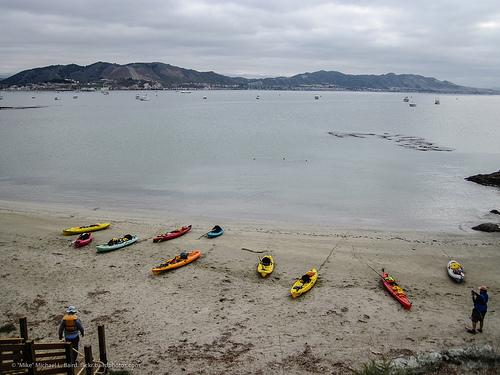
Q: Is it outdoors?
A: Yes, it is outdoors.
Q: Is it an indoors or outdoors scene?
A: It is outdoors.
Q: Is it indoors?
A: No, it is outdoors.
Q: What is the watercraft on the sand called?
A: The watercraft is a canoe.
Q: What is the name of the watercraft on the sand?
A: The watercraft is a canoe.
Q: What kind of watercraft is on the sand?
A: The watercraft is a canoe.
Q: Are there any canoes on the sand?
A: Yes, there is a canoe on the sand.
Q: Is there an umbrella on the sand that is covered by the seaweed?
A: No, there is a canoe on the sand.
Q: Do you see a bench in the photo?
A: No, there are no benches.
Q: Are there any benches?
A: No, there are no benches.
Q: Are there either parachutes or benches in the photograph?
A: No, there are no benches or parachutes.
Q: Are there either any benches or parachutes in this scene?
A: No, there are no benches or parachutes.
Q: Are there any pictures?
A: No, there are no pictures.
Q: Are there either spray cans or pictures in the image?
A: No, there are no pictures or spray cans.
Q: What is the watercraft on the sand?
A: The watercraft is a canoe.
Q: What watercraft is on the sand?
A: The watercraft is a canoe.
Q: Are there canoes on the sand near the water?
A: Yes, there is a canoe on the sand.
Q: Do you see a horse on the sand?
A: No, there is a canoe on the sand.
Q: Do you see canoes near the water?
A: Yes, there is a canoe near the water.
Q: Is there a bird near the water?
A: No, there is a canoe near the water.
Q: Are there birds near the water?
A: No, there is a canoe near the water.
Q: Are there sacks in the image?
A: No, there are no sacks.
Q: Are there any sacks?
A: No, there are no sacks.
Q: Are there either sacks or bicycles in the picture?
A: No, there are no sacks or bicycles.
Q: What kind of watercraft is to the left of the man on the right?
A: The watercraft is a canoe.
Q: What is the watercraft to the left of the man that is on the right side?
A: The watercraft is a canoe.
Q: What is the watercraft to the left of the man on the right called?
A: The watercraft is a canoe.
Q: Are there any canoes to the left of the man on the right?
A: Yes, there is a canoe to the left of the man.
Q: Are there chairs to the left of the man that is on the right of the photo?
A: No, there is a canoe to the left of the man.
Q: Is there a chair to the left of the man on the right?
A: No, there is a canoe to the left of the man.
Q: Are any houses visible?
A: No, there are no houses.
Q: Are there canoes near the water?
A: Yes, there is a canoe near the water.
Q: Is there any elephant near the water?
A: No, there is a canoe near the water.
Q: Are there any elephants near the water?
A: No, there is a canoe near the water.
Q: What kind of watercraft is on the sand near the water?
A: The watercraft is a canoe.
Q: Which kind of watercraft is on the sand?
A: The watercraft is a canoe.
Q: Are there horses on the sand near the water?
A: No, there is a canoe on the sand.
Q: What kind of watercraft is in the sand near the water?
A: The watercraft is a canoe.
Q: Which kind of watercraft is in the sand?
A: The watercraft is a canoe.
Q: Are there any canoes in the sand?
A: Yes, there is a canoe in the sand.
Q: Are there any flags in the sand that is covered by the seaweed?
A: No, there is a canoe in the sand.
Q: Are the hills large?
A: Yes, the hills are large.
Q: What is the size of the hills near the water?
A: The hills are large.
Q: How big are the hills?
A: The hills are large.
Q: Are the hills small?
A: No, the hills are large.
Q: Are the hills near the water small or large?
A: The hills are large.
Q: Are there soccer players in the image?
A: No, there are no soccer players.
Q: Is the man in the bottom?
A: Yes, the man is in the bottom of the image.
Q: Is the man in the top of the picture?
A: No, the man is in the bottom of the image.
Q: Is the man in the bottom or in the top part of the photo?
A: The man is in the bottom of the image.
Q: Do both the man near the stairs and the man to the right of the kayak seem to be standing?
A: Yes, both the man and the man are standing.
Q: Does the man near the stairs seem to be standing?
A: Yes, the man is standing.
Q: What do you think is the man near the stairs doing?
A: The man is standing.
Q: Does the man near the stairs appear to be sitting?
A: No, the man is standing.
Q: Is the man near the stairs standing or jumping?
A: The man is standing.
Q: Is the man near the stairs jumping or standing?
A: The man is standing.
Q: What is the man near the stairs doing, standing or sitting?
A: The man is standing.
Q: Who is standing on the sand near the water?
A: The man is standing on the sand.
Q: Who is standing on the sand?
A: The man is standing on the sand.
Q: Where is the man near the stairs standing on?
A: The man is standing on the sand.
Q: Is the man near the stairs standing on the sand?
A: Yes, the man is standing on the sand.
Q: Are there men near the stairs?
A: Yes, there is a man near the stairs.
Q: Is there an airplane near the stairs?
A: No, there is a man near the stairs.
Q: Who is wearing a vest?
A: The man is wearing a vest.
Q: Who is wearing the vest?
A: The man is wearing a vest.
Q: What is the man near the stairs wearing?
A: The man is wearing a vest.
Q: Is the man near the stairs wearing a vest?
A: Yes, the man is wearing a vest.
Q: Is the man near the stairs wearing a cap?
A: No, the man is wearing a vest.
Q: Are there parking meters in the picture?
A: No, there are no parking meters.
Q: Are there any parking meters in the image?
A: No, there are no parking meters.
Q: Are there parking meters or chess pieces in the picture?
A: No, there are no parking meters or chess pieces.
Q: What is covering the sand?
A: The seaweed is covering the sand.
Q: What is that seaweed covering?
A: The seaweed is covering the sand.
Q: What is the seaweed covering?
A: The seaweed is covering the sand.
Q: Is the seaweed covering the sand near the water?
A: Yes, the seaweed is covering the sand.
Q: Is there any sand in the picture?
A: Yes, there is sand.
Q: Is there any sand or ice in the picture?
A: Yes, there is sand.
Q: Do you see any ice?
A: No, there is no ice.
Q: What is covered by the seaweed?
A: The sand is covered by the seaweed.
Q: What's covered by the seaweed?
A: The sand is covered by the seaweed.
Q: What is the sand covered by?
A: The sand is covered by the sea weed.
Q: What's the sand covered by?
A: The sand is covered by the sea weed.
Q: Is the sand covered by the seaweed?
A: Yes, the sand is covered by the seaweed.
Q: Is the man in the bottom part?
A: Yes, the man is in the bottom of the image.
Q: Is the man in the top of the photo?
A: No, the man is in the bottom of the image.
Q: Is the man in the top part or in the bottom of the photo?
A: The man is in the bottom of the image.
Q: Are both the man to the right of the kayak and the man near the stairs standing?
A: Yes, both the man and the man are standing.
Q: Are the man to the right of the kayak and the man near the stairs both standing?
A: Yes, both the man and the man are standing.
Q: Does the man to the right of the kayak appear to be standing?
A: Yes, the man is standing.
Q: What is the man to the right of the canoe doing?
A: The man is standing.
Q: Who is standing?
A: The man is standing.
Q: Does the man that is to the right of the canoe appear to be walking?
A: No, the man is standing.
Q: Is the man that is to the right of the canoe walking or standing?
A: The man is standing.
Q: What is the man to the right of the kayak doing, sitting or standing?
A: The man is standing.